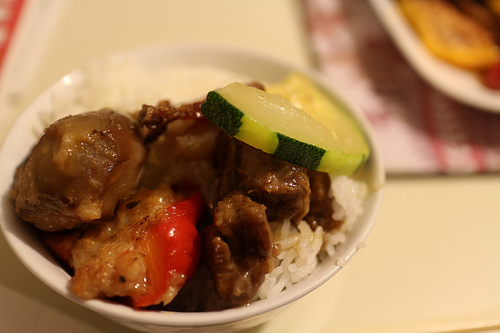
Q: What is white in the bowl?
A: Rice.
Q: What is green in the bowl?
A: A cucumber.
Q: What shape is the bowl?
A: Round.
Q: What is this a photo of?
A: Food.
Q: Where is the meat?
A: In a bowl.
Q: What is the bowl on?
A: A table.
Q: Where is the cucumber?
A: On top of the meat.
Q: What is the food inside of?
A: A bowl.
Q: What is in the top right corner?
A: A plate.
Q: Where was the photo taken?
A: Inside a building.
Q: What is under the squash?
A: Chicken meat.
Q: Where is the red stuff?
A: On the chicken.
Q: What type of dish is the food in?
A: Monkey dish.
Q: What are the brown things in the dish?
A: Meat chunks.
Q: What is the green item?
A: Cucumber.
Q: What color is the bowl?
A: White.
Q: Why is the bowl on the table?
A: To hold food.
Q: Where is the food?
A: In a bowl.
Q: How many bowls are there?
A: One.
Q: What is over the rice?
A: Meat and veggies.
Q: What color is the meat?
A: Brown.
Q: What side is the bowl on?
A: Left side.